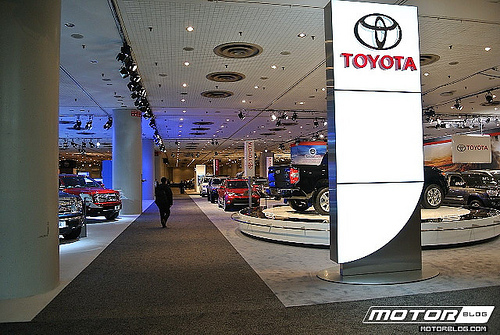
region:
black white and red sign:
[311, 7, 428, 289]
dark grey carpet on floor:
[101, 200, 268, 332]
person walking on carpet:
[146, 173, 172, 220]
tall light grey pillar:
[3, 13, 58, 303]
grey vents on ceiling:
[192, 40, 244, 126]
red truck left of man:
[58, 160, 127, 221]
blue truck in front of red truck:
[50, 192, 91, 232]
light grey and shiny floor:
[257, 222, 374, 305]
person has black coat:
[152, 182, 169, 205]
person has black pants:
[155, 204, 171, 227]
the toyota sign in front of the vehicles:
[322, 3, 429, 275]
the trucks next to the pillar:
[40, 155, 129, 235]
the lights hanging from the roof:
[115, 46, 154, 116]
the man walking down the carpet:
[153, 169, 177, 231]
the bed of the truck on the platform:
[264, 157, 327, 219]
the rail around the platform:
[232, 209, 327, 239]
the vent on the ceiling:
[215, 35, 263, 66]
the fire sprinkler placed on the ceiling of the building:
[226, 23, 253, 38]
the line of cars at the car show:
[192, 176, 264, 213]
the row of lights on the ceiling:
[172, 17, 198, 177]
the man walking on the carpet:
[153, 165, 176, 234]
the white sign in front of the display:
[330, 1, 427, 281]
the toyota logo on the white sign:
[339, 11, 421, 83]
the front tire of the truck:
[423, 182, 445, 208]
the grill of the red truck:
[90, 191, 120, 207]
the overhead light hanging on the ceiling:
[426, 88, 498, 127]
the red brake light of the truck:
[288, 166, 301, 188]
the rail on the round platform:
[438, 218, 498, 255]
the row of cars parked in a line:
[198, 167, 254, 214]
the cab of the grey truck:
[441, 170, 498, 214]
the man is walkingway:
[152, 180, 193, 231]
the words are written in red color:
[339, 48, 421, 69]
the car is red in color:
[228, 175, 246, 200]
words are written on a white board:
[336, 49, 417, 86]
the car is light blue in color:
[57, 189, 87, 237]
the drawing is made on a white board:
[354, 7, 414, 49]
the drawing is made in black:
[356, 13, 401, 45]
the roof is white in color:
[146, 11, 204, 52]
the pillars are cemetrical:
[15, 151, 62, 281]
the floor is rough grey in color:
[151, 250, 206, 326]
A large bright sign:
[317, 0, 441, 285]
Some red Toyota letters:
[340, 51, 416, 70]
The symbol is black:
[352, 13, 400, 50]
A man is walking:
[154, 177, 174, 229]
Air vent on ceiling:
[214, 41, 262, 59]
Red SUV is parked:
[59, 172, 120, 219]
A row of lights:
[117, 44, 166, 153]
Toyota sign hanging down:
[450, 133, 490, 163]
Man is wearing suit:
[155, 177, 172, 229]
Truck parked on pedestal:
[270, 152, 446, 213]